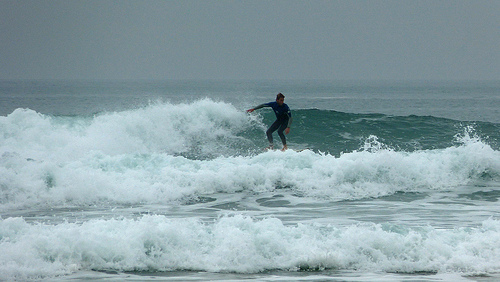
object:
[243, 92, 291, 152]
man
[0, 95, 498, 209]
waves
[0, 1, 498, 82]
sky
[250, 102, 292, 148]
wetsuit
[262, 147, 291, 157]
man's surfboard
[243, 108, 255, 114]
right hand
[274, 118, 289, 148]
legs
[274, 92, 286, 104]
head